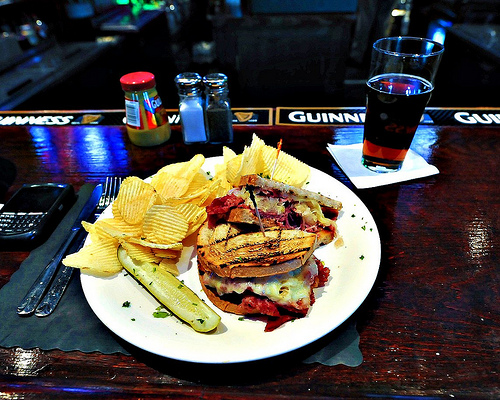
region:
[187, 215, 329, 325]
Sandwich on the plate.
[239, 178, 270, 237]
toothpick in the sandwhich.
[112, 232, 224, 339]
Pickle on the plate.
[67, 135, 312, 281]
Potato chips on the plate.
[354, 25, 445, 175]
Drink on the bar.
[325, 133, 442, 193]
napkin under the drink.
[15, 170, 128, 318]
Knife and fork on the table.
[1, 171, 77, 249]
Cell phone on the bar.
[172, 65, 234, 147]
Salt and pepper shakers.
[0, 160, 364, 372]
Greenish gray place mat under the plate.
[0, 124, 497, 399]
section of a dark, highly polished, wooden table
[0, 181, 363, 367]
partially visible black paper place-mat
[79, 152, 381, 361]
pastrami sandwich on a round white plate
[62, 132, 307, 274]
potato chips with ruffles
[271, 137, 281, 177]
toothpick with an orange top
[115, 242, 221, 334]
long slice of a pickle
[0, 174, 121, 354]
knife sitting beside fork on place-mat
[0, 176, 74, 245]
black cellular phone with several buttons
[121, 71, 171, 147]
yellow condiment in a closed jar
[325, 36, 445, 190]
glass of dark liquid on a white napkin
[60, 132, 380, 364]
The plate is full of food.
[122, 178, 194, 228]
Chips are on the plate.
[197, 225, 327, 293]
A sandwich is on the plate.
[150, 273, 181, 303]
A pickle is on the plate.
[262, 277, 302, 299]
Melted cheese is in the sandwich.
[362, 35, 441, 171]
A glass is next to the plate.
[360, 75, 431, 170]
The glass contains a beverage.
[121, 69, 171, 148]
Mustard is on the table.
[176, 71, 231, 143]
Salt and pepper shakers are on the table.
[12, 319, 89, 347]
A green placemat is under the plate.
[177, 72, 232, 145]
a salt and pepper shaker on a table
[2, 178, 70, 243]
a cell phone on a table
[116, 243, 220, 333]
a slice of pickle on a plate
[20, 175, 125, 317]
a fork and a knife on a green place mat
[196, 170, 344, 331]
two halves of a sandwich on a plate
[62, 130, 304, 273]
a bunch of ruffle chips on a plate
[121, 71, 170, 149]
a glass jar of Dijon mustard on a table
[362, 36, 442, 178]
a glass of soda on a napkin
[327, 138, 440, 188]
a white folded napkin on a table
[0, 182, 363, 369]
a green place mat on a table